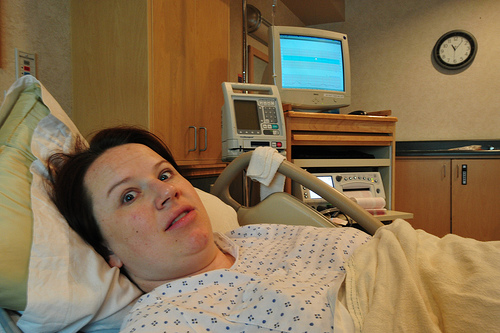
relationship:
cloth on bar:
[243, 133, 281, 193] [285, 155, 369, 228]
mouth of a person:
[162, 200, 201, 233] [42, 124, 484, 331]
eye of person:
[107, 184, 136, 204] [71, 112, 497, 296]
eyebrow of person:
[100, 164, 133, 189] [40, 146, 480, 330]